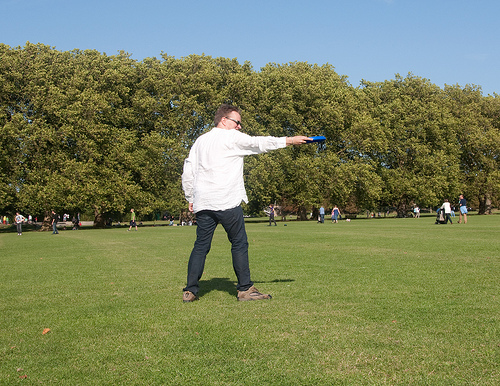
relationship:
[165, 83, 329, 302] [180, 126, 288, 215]
man wearing shirt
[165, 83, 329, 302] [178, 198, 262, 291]
man wearing blue jeans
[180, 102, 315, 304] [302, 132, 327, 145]
man holds frisbee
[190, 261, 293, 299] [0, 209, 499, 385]
shadow in green grass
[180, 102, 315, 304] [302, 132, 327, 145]
man throwing frisbee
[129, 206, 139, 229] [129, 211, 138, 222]
person wearing green shirt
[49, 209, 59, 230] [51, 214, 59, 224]
person wearing black shirt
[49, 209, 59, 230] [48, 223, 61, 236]
person wearing blue jeans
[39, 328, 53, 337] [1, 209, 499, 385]
brown leaf on green grass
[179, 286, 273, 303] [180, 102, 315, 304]
shoe on man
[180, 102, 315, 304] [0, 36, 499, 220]
man standing by tree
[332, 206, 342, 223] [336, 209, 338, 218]
woman wearing blue sun dress